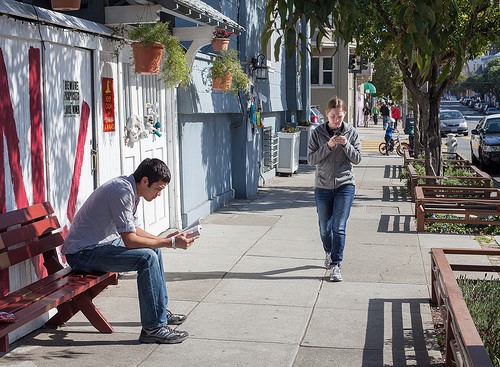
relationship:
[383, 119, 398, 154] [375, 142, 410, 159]
kid riding bike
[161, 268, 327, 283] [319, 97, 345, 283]
shadow of woman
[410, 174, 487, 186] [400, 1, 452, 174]
fence surrounding tree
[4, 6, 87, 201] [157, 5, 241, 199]
wall of building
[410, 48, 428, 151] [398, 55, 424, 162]
tree in background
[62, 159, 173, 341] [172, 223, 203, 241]
man reading book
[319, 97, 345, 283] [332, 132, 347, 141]
woman reading phone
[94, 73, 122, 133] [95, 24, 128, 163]
sign on building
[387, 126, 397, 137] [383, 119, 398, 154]
shirt on boy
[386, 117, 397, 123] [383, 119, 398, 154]
helmet on kid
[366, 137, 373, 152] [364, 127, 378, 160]
lines on street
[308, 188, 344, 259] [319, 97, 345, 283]
jeans on woman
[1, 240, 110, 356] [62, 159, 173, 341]
bench supporting man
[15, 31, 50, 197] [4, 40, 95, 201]
stripe on doors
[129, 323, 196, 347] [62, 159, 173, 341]
shoe on man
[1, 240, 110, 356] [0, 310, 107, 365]
bench on ground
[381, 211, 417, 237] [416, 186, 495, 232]
shadow of fence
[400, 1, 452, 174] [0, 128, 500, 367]
tree on pavement